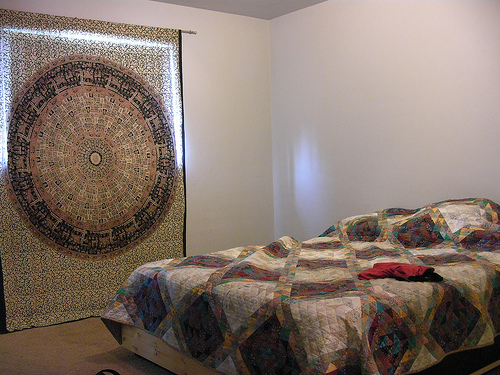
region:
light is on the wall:
[228, 114, 347, 212]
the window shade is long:
[5, 7, 200, 339]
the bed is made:
[104, 167, 497, 374]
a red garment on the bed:
[339, 238, 454, 299]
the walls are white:
[180, 22, 475, 184]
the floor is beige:
[15, 311, 109, 360]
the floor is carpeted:
[3, 327, 103, 362]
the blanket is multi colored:
[154, 188, 487, 370]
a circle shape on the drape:
[11, 48, 169, 249]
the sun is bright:
[0, 22, 218, 194]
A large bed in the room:
[96, 193, 497, 373]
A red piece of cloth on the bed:
[353, 255, 447, 286]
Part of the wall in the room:
[326, 94, 397, 153]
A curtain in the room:
[0, 5, 200, 336]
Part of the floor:
[36, 333, 74, 366]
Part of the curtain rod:
[177, 25, 199, 35]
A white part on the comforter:
[305, 307, 349, 334]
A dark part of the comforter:
[187, 307, 209, 342]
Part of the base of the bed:
[126, 337, 148, 345]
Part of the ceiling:
[248, 3, 277, 10]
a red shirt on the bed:
[358, 256, 443, 298]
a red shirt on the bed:
[325, 230, 452, 313]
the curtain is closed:
[10, 7, 198, 328]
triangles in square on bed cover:
[417, 273, 487, 365]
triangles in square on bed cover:
[354, 290, 416, 373]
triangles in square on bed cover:
[229, 296, 314, 370]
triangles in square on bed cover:
[171, 285, 239, 364]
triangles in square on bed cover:
[127, 265, 178, 331]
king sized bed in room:
[90, 135, 496, 371]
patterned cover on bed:
[116, 162, 488, 364]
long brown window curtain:
[0, 3, 200, 346]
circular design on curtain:
[9, 43, 185, 261]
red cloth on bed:
[359, 242, 449, 294]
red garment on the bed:
[353, 260, 439, 285]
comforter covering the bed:
[96, 193, 499, 372]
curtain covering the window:
[0, 8, 186, 333]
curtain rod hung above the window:
[181, 27, 208, 42]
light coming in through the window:
[2, 20, 189, 169]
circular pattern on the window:
[2, 46, 183, 266]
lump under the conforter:
[333, 182, 494, 268]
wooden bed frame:
[117, 326, 215, 373]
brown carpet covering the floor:
[0, 310, 143, 373]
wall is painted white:
[183, 103, 498, 249]